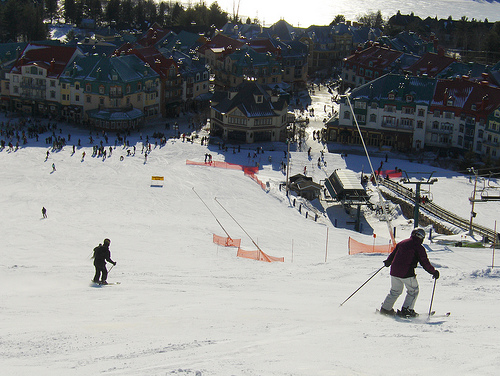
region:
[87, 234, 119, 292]
a skier in silhouette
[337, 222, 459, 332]
a skier wearing red and white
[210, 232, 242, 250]
protective orange netting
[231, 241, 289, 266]
protective orange netting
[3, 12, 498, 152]
a large town below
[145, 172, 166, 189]
a red white and blue flag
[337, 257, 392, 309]
a black ski pole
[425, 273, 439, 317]
a black ski pole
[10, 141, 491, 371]
a snow slope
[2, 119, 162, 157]
spectators at bottom of hill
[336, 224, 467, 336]
Skier on the side of a slope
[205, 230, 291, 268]
Orange safety fence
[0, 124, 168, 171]
Many skiers at the bottom of a slope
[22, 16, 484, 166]
Buildings by ski slopes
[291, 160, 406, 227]
Ski slope chair lift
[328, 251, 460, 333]
Two ski poles and two skis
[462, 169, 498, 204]
Chair lift up in the air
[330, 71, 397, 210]
Wires up in the air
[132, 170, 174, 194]
Caution sign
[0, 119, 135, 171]
People in the shadow of a building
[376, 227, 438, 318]
snowboarder in a purple sweater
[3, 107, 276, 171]
bunch of people in the back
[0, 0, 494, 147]
bunch of cabins in the back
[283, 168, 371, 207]
little ski station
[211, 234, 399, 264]
for red fences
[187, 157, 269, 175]
red fences in the back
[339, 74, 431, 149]
white cabin with green roof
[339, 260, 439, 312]
two ski poles in the snowboarder in the right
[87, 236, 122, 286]
snowboarder in the left with black suit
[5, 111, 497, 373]
white snow on the floor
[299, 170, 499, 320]
a person skiing on the snow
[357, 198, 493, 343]
a person skiing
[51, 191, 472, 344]
two people skiing in the snow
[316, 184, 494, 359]
a person skiing during the day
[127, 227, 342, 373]
white snow on the ground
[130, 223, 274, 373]
white snow covering the ground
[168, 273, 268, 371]
snow covering the ground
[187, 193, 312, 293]
an orange barrier in the snow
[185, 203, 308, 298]
a barrier in the snow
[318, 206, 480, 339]
a person with a helmet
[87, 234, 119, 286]
Person in black clothes skiing.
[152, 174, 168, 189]
flag sitting in the snow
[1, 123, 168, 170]
crowd of people on the bottom of ski slope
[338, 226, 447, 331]
skier wearing a black and white helmet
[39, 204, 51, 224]
person standing at bottom of ski slope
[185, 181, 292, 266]
two orange barriers on a ski slope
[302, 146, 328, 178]
crowd standing near ski lift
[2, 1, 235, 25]
trees behind houses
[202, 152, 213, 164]
two people standing behind orange barrier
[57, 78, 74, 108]
a yellow house